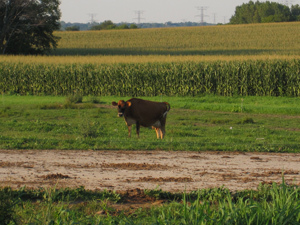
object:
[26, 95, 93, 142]
grass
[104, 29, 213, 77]
field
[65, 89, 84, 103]
shrub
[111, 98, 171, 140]
cow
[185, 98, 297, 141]
grass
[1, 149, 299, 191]
path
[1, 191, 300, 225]
grass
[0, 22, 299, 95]
corn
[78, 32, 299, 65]
tassels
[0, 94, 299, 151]
grass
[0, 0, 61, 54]
leaves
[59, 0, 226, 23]
sky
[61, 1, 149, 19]
cloud